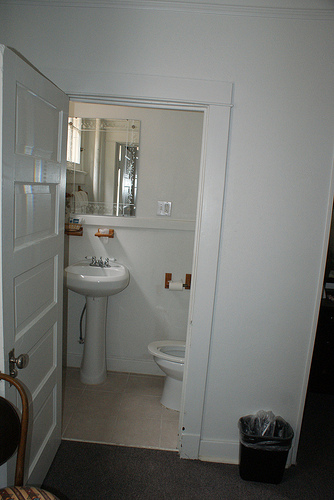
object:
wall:
[234, 16, 308, 305]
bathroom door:
[0, 44, 70, 490]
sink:
[63, 256, 131, 297]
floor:
[61, 366, 180, 450]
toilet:
[147, 340, 185, 412]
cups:
[99, 228, 109, 245]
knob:
[85, 255, 92, 260]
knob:
[105, 256, 117, 262]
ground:
[109, 470, 235, 499]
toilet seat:
[147, 339, 186, 366]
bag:
[236, 409, 294, 451]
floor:
[39, 437, 332, 500]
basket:
[237, 413, 294, 486]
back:
[0, 369, 30, 486]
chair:
[0, 372, 60, 500]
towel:
[137, 346, 177, 403]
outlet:
[156, 201, 172, 217]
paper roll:
[169, 281, 184, 291]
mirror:
[65, 115, 141, 219]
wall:
[149, 117, 189, 202]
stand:
[79, 295, 109, 385]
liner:
[242, 415, 294, 437]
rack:
[165, 272, 192, 289]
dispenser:
[161, 269, 194, 293]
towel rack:
[66, 185, 89, 198]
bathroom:
[61, 93, 205, 452]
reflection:
[64, 116, 132, 211]